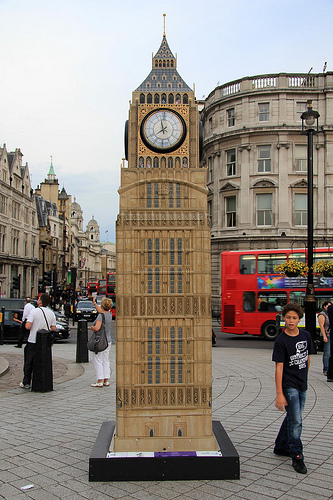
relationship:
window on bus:
[254, 291, 289, 312] [215, 235, 327, 334]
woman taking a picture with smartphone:
[89, 293, 113, 387] [86, 295, 92, 299]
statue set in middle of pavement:
[90, 33, 265, 358] [15, 374, 315, 496]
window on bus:
[242, 131, 281, 179] [204, 236, 326, 333]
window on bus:
[240, 252, 258, 274] [218, 244, 332, 341]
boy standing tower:
[272, 300, 312, 462] [115, 18, 232, 459]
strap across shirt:
[36, 304, 51, 332] [26, 306, 55, 342]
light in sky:
[16, 19, 89, 148] [0, 5, 332, 241]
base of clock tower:
[87, 418, 240, 480] [111, 11, 219, 454]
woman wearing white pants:
[89, 293, 113, 387] [90, 339, 114, 378]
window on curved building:
[252, 188, 275, 227] [198, 61, 331, 317]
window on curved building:
[292, 188, 311, 226] [198, 61, 331, 317]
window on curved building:
[253, 100, 272, 122] [198, 61, 331, 317]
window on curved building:
[223, 105, 237, 126] [198, 61, 331, 317]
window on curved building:
[219, 193, 239, 230] [198, 61, 331, 317]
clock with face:
[129, 96, 198, 169] [139, 106, 187, 154]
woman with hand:
[89, 293, 113, 387] [89, 292, 101, 309]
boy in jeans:
[272, 304, 324, 416] [272, 388, 304, 455]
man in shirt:
[24, 285, 60, 379] [26, 306, 55, 342]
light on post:
[293, 101, 319, 353] [302, 133, 315, 352]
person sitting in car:
[13, 312, 23, 322] [53, 273, 123, 340]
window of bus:
[241, 252, 258, 272] [218, 248, 328, 330]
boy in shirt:
[272, 300, 312, 462] [270, 329, 318, 392]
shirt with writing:
[270, 329, 318, 392] [288, 352, 307, 371]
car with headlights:
[74, 298, 98, 319] [76, 308, 97, 313]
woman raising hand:
[89, 293, 113, 387] [92, 295, 96, 302]